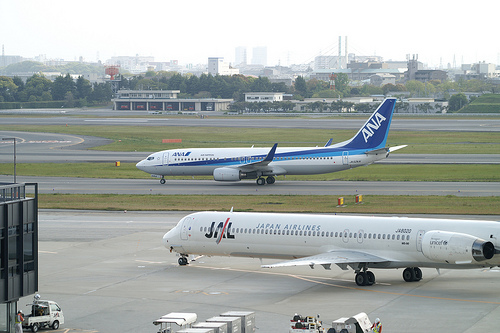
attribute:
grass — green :
[0, 157, 497, 180]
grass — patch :
[336, 174, 491, 228]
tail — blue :
[346, 89, 411, 171]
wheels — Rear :
[340, 262, 460, 306]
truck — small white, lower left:
[21, 296, 64, 331]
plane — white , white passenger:
[160, 209, 499, 286]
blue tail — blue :
[340, 97, 408, 171]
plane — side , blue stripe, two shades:
[128, 55, 453, 185]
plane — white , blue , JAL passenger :
[135, 99, 409, 188]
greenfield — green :
[421, 137, 451, 149]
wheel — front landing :
[249, 171, 286, 189]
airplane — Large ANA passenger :
[135, 97, 410, 182]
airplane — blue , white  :
[132, 95, 412, 188]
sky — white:
[249, 23, 401, 62]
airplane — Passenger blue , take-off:
[125, 82, 424, 187]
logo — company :
[203, 213, 236, 240]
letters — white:
[355, 108, 390, 146]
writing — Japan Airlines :
[203, 217, 237, 243]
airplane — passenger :
[167, 201, 483, 284]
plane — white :
[156, 193, 482, 286]